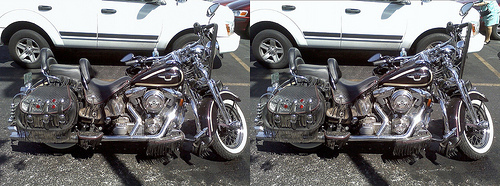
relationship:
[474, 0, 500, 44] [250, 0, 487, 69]
woman near car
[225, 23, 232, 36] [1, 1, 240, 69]
orange light on car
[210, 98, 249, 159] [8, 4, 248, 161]
wheel on bike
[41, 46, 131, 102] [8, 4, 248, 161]
seat on bike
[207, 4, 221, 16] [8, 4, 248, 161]
mirror on bike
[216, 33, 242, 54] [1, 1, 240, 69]
bumper of car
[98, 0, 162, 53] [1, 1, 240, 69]
door on car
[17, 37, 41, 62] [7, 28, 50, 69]
rim of wheel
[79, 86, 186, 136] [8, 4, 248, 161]
engine of bike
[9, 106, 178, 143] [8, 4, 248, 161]
exhaust pipe on bike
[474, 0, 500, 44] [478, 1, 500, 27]
woman in dress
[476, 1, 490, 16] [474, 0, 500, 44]
handbag carried by woman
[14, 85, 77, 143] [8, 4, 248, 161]
saddlebag on bike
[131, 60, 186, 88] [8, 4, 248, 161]
gas tank on bike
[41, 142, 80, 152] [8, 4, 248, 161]
rear wheel on bike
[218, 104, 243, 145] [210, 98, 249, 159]
spokes on wheel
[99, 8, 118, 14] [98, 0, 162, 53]
door handles on door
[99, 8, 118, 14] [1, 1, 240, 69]
door handles on car